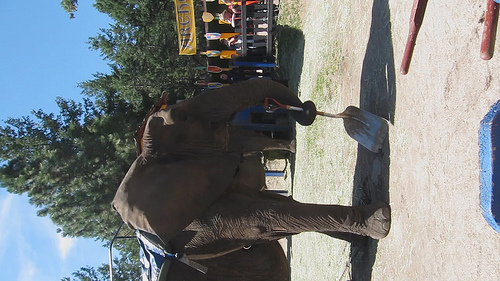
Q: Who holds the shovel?
A: An elephant.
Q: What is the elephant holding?
A: A shovel.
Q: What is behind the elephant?
A: The tallest tree in the photo.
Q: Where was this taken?
A: Circus.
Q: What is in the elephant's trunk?
A: Shovel.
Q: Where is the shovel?
A: In the elephant's trunk.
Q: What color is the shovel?
A: Silver.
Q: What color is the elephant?
A: Gray.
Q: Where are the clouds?
A: In the sky.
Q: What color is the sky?
A: Blue.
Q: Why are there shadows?
A: Sunny.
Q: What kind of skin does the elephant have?
A: Wrinkled.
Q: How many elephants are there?
A: 1.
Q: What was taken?
A: Picture.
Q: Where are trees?
A: Behind elephant.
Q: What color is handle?
A: Red.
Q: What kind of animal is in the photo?
A: An elephant.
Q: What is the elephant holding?
A: A shovel.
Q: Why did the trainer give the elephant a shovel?
A: To dig.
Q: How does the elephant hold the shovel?
A: With its trunk.